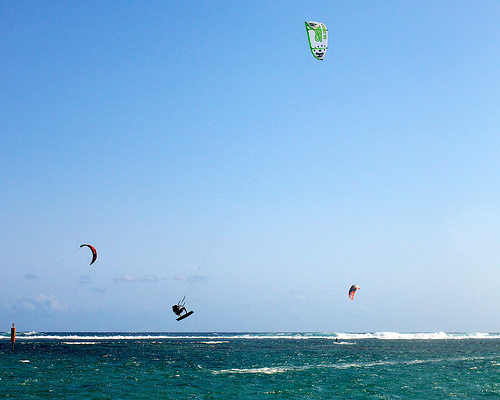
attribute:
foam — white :
[7, 333, 454, 341]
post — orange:
[8, 323, 15, 345]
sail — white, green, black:
[300, 17, 330, 62]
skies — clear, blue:
[5, 35, 490, 347]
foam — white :
[213, 354, 496, 369]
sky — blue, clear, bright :
[0, 3, 490, 330]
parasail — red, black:
[77, 241, 102, 267]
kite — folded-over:
[78, 242, 98, 266]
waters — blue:
[0, 329, 499, 399]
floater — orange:
[4, 322, 19, 344]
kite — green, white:
[299, 14, 343, 62]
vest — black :
[173, 304, 189, 314]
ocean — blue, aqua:
[131, 337, 372, 396]